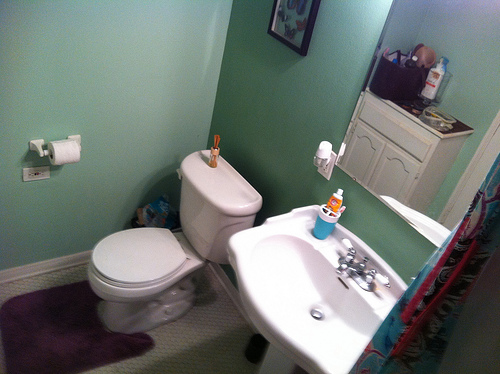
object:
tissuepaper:
[45, 139, 82, 166]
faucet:
[336, 237, 368, 275]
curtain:
[350, 156, 500, 373]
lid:
[90, 226, 189, 284]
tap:
[343, 252, 372, 279]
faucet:
[359, 266, 392, 292]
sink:
[227, 203, 423, 372]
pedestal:
[255, 342, 297, 373]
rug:
[4, 279, 157, 373]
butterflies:
[283, 23, 296, 39]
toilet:
[87, 149, 265, 336]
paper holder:
[29, 135, 82, 158]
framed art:
[267, 0, 326, 55]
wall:
[207, 0, 455, 290]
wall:
[0, 1, 233, 281]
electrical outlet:
[23, 165, 51, 181]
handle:
[372, 270, 392, 288]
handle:
[340, 237, 356, 255]